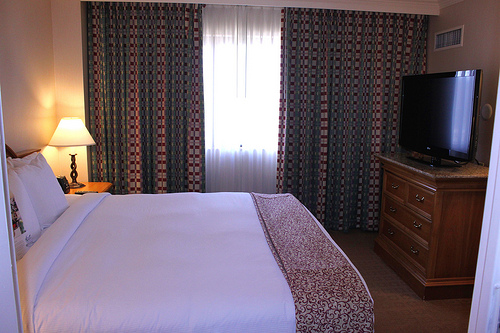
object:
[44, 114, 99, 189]
lamp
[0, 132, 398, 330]
bed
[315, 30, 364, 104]
curtain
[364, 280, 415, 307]
floor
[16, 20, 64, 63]
wall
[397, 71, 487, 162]
tv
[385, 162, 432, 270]
dresser